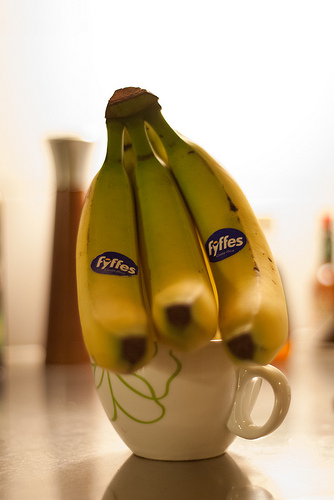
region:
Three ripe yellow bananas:
[76, 85, 286, 370]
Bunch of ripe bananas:
[74, 86, 287, 370]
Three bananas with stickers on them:
[74, 86, 285, 370]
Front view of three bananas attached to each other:
[74, 86, 286, 366]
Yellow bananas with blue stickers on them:
[75, 86, 287, 370]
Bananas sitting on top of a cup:
[74, 86, 290, 460]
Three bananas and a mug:
[75, 86, 291, 461]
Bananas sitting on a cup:
[75, 86, 290, 460]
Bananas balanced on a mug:
[74, 86, 290, 460]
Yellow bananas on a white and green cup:
[75, 86, 291, 460]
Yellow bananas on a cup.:
[67, 85, 284, 375]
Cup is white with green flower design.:
[79, 340, 286, 455]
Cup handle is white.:
[223, 360, 293, 440]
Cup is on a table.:
[4, 335, 332, 497]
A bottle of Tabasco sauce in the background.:
[310, 207, 332, 346]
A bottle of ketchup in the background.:
[41, 130, 83, 369]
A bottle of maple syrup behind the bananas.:
[255, 214, 287, 360]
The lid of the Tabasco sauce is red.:
[319, 210, 332, 227]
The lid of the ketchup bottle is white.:
[42, 132, 89, 189]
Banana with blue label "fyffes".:
[87, 249, 139, 278]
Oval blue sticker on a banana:
[89, 250, 138, 278]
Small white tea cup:
[85, 337, 290, 462]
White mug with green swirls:
[84, 338, 291, 462]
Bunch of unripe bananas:
[73, 85, 291, 373]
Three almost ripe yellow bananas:
[70, 85, 292, 374]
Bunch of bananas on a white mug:
[71, 86, 291, 461]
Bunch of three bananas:
[71, 86, 290, 375]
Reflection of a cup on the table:
[95, 452, 262, 498]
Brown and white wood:
[37, 132, 96, 368]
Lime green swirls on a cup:
[83, 346, 184, 427]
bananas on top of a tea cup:
[64, 82, 293, 461]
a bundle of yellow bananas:
[65, 84, 299, 370]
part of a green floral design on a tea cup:
[95, 373, 179, 424]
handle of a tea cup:
[228, 360, 291, 441]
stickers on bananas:
[85, 226, 258, 277]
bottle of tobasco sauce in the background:
[309, 208, 331, 331]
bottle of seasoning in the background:
[37, 128, 91, 368]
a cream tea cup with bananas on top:
[78, 327, 291, 460]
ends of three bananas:
[113, 302, 258, 367]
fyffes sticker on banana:
[201, 225, 249, 262]